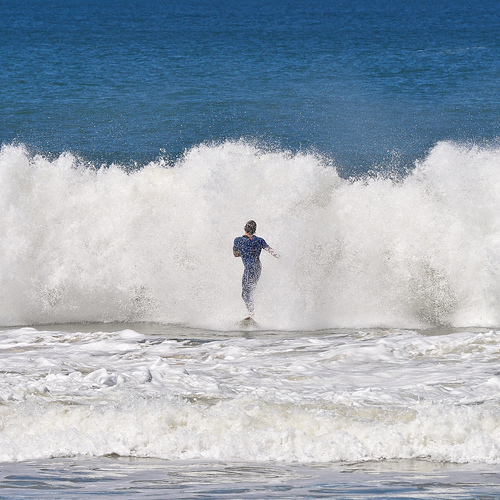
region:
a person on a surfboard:
[222, 205, 287, 375]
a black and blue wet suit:
[220, 222, 308, 318]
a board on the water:
[216, 302, 278, 339]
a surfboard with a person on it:
[233, 307, 279, 342]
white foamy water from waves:
[22, 315, 499, 469]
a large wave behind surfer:
[15, 127, 466, 311]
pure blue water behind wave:
[7, 5, 497, 148]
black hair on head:
[232, 215, 259, 236]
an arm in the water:
[262, 239, 345, 276]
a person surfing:
[209, 203, 331, 355]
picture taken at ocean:
[16, 18, 485, 483]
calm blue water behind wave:
[119, 22, 433, 102]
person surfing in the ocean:
[204, 217, 299, 333]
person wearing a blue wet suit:
[206, 213, 300, 335]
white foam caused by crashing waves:
[60, 395, 485, 482]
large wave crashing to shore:
[20, 135, 486, 324]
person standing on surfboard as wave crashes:
[218, 207, 288, 338]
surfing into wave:
[224, 207, 291, 337]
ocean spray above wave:
[336, 100, 402, 163]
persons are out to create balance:
[251, 238, 293, 272]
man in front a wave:
[215, 208, 293, 339]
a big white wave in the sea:
[0, 131, 497, 369]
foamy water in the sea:
[0, 318, 494, 495]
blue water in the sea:
[7, 9, 489, 117]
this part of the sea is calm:
[2, 0, 492, 127]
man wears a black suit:
[224, 215, 284, 329]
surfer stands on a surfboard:
[222, 208, 290, 339]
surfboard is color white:
[227, 313, 271, 337]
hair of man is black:
[228, 211, 269, 253]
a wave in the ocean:
[7, 9, 498, 499]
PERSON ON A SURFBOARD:
[211, 209, 292, 341]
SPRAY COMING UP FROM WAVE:
[5, 125, 492, 208]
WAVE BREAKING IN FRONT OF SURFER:
[2, 339, 489, 473]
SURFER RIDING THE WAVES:
[223, 213, 284, 342]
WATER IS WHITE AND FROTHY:
[7, 330, 486, 449]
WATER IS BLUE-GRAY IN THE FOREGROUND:
[2, 460, 493, 496]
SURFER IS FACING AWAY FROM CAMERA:
[221, 215, 288, 331]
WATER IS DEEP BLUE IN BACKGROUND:
[5, 4, 493, 149]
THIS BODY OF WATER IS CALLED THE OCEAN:
[6, 11, 492, 342]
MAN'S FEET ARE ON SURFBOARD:
[220, 300, 281, 340]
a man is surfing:
[214, 198, 286, 350]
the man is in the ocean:
[6, 7, 473, 447]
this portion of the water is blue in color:
[32, 13, 487, 131]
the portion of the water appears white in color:
[18, 314, 481, 468]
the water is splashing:
[16, 148, 489, 320]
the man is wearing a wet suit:
[228, 237, 277, 312]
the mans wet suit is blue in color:
[236, 235, 268, 308]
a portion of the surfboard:
[235, 314, 264, 337]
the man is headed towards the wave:
[208, 158, 278, 339]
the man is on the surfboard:
[209, 196, 284, 341]